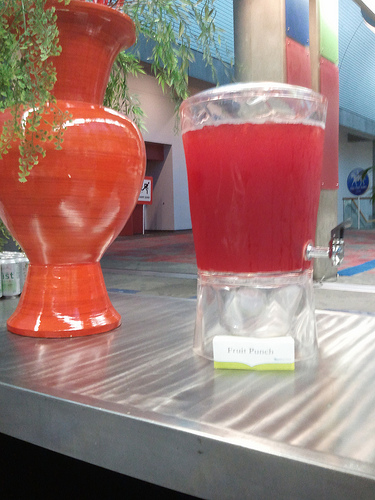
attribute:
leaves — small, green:
[1, 0, 237, 186]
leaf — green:
[197, 8, 216, 42]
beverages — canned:
[1, 256, 22, 301]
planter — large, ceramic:
[6, 40, 135, 354]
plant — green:
[3, 109, 79, 190]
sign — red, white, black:
[105, 161, 180, 227]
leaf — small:
[22, 97, 337, 274]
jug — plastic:
[178, 75, 343, 373]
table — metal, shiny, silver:
[2, 279, 374, 497]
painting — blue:
[344, 166, 371, 198]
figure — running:
[141, 181, 151, 194]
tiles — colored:
[285, 4, 372, 89]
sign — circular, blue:
[344, 162, 369, 198]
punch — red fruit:
[175, 116, 329, 278]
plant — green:
[2, 5, 64, 187]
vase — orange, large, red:
[2, 4, 149, 346]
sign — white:
[212, 331, 297, 371]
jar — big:
[169, 73, 339, 379]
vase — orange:
[6, 8, 151, 317]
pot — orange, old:
[26, 21, 146, 301]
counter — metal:
[88, 376, 227, 460]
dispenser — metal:
[192, 88, 358, 304]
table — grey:
[91, 364, 187, 434]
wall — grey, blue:
[341, 72, 355, 136]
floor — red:
[148, 236, 186, 265]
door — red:
[125, 214, 148, 234]